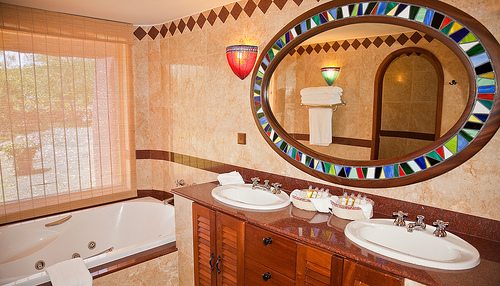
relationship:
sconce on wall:
[219, 36, 275, 83] [132, 0, 499, 240]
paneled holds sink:
[169, 166, 500, 286] [344, 211, 486, 277]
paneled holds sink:
[169, 166, 496, 284] [207, 175, 292, 214]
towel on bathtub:
[43, 256, 92, 284] [0, 195, 175, 286]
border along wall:
[135, 148, 499, 238] [132, 0, 499, 240]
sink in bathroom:
[207, 140, 495, 269] [1, 0, 499, 283]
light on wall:
[223, 44, 259, 80] [148, 0, 498, 221]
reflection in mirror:
[268, 21, 469, 161] [271, 23, 473, 173]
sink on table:
[356, 223, 473, 264] [173, 180, 496, 284]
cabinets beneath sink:
[167, 190, 357, 283] [208, 170, 293, 214]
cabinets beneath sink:
[167, 190, 357, 283] [342, 202, 484, 281]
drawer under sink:
[242, 228, 289, 260] [356, 215, 463, 270]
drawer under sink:
[241, 259, 278, 284] [356, 215, 463, 270]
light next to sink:
[223, 44, 259, 80] [201, 155, 283, 215]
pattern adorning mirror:
[249, 0, 497, 152] [265, 17, 475, 161]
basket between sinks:
[284, 174, 324, 218] [170, 134, 487, 284]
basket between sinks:
[330, 177, 377, 220] [170, 134, 487, 284]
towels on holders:
[296, 82, 348, 109] [300, 101, 346, 112]